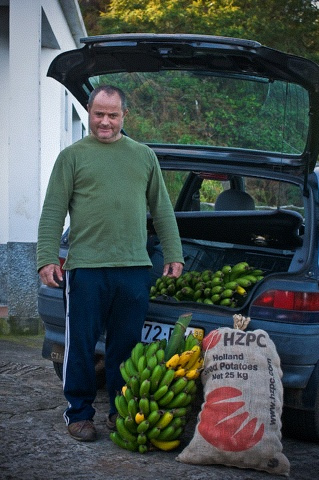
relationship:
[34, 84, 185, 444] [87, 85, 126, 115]
man has hair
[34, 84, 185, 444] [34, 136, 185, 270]
man has shirt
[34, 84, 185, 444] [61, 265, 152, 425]
man has pants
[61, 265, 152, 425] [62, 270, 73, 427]
pants have stripe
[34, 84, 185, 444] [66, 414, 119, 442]
man has shoes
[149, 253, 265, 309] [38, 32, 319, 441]
bananas in car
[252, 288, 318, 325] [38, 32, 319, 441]
tail lights on car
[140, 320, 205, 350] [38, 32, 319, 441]
license plate on car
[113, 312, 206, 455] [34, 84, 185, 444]
bananas by man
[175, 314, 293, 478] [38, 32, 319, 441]
sack in front of car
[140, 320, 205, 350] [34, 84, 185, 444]
license plate by man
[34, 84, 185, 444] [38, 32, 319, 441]
man by car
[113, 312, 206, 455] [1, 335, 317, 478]
bananas on ground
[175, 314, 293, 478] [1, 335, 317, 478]
sack on ground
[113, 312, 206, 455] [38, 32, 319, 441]
bananas against car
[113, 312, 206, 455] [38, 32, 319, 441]
bananas in car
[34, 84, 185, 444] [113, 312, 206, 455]
man by bananas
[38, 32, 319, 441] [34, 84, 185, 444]
car behind man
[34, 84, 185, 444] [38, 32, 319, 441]
man in front of car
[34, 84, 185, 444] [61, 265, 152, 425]
man wearing pants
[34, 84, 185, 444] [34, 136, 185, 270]
man wearing shirt